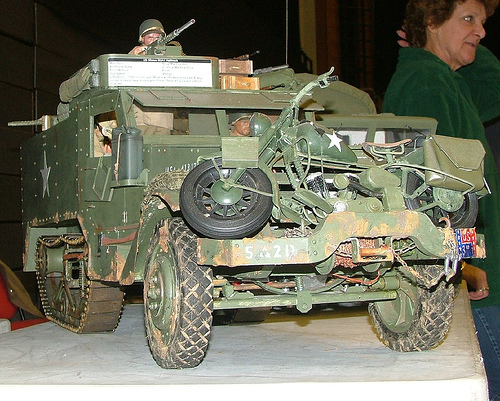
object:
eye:
[459, 13, 476, 23]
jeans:
[473, 307, 500, 399]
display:
[1, 16, 491, 398]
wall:
[0, 0, 388, 317]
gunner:
[120, 14, 193, 61]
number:
[245, 237, 308, 264]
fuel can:
[111, 125, 146, 182]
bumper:
[192, 209, 488, 263]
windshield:
[127, 90, 305, 135]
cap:
[134, 17, 168, 41]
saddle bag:
[417, 128, 488, 195]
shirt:
[383, 45, 500, 303]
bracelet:
[445, 253, 459, 279]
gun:
[134, 20, 197, 55]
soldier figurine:
[129, 18, 183, 55]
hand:
[452, 261, 493, 301]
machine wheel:
[368, 261, 454, 357]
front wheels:
[141, 212, 218, 371]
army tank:
[14, 16, 489, 369]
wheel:
[176, 151, 273, 240]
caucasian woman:
[384, 2, 500, 400]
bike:
[179, 69, 493, 239]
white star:
[37, 150, 57, 200]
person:
[379, 1, 499, 398]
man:
[229, 110, 254, 138]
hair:
[399, 1, 484, 42]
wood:
[0, 0, 383, 346]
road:
[1, 279, 485, 395]